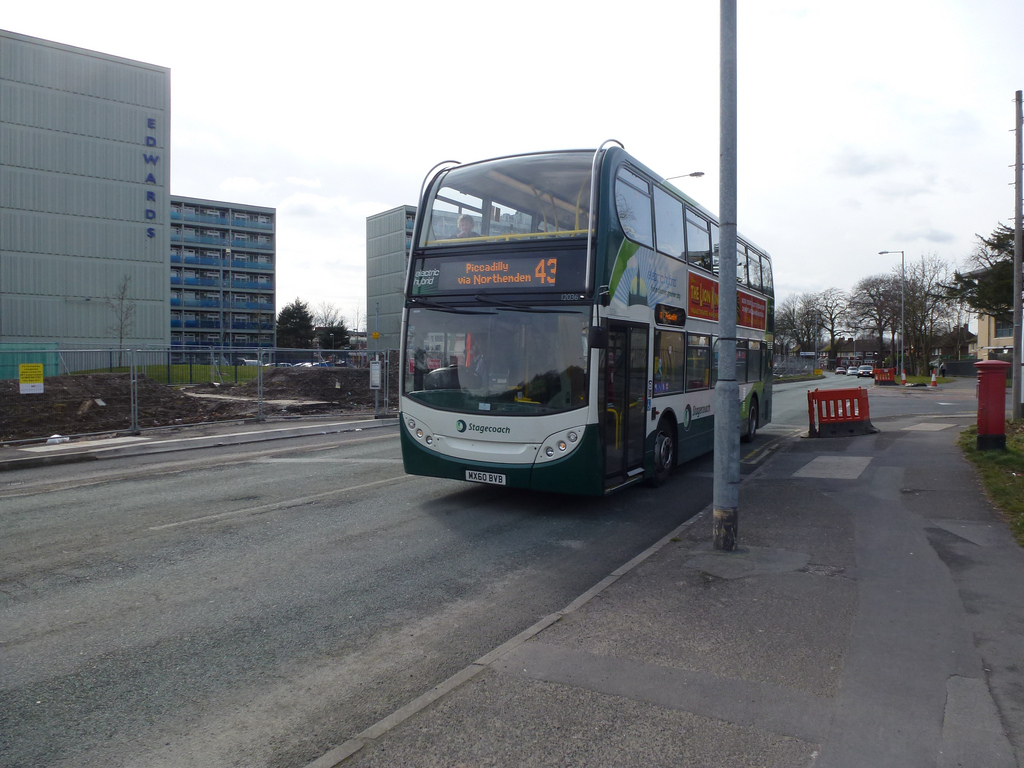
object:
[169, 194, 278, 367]
building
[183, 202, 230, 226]
balcony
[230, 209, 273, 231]
balcony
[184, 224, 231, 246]
balcony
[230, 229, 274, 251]
balcony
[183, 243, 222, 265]
balcony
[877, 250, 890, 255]
light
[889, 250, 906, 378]
light pole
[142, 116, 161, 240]
word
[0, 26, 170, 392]
wall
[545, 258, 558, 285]
characters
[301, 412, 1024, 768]
sidewalk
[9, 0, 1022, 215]
sky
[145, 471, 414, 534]
lines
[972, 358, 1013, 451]
pillar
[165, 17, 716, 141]
clouds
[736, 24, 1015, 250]
clouds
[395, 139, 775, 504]
bus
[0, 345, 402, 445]
fence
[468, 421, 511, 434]
writing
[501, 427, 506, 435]
letters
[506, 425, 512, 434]
letters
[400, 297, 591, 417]
windshield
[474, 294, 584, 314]
wipers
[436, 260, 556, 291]
sign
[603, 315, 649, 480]
door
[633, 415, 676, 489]
wheel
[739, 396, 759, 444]
wheel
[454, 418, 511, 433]
logo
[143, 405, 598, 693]
street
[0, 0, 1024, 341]
sky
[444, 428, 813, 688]
curb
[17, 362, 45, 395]
sign